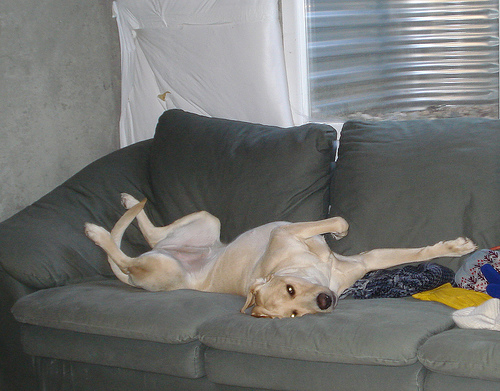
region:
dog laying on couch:
[83, 25, 482, 387]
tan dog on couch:
[3, 134, 335, 379]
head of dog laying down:
[226, 259, 355, 340]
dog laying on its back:
[8, 113, 424, 340]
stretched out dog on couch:
[46, 119, 421, 308]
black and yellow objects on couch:
[377, 270, 499, 321]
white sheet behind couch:
[61, 0, 355, 137]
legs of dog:
[317, 166, 437, 269]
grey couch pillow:
[145, 91, 342, 243]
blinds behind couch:
[273, 16, 477, 144]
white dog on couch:
[84, 191, 441, 327]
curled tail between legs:
[101, 190, 154, 277]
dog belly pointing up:
[196, 215, 296, 278]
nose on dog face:
[311, 279, 338, 318]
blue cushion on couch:
[145, 108, 342, 223]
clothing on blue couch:
[349, 242, 497, 315]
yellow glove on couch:
[408, 274, 495, 310]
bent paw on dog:
[293, 208, 360, 248]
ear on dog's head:
[236, 275, 268, 323]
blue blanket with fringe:
[348, 258, 456, 303]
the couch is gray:
[347, 317, 362, 349]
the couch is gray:
[319, 328, 332, 343]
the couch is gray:
[353, 363, 363, 373]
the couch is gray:
[367, 360, 375, 380]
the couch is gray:
[346, 337, 363, 377]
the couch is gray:
[338, 358, 354, 388]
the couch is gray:
[354, 339, 369, 371]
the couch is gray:
[355, 340, 375, 383]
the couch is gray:
[360, 325, 377, 368]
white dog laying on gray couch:
[58, 181, 488, 385]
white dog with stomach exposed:
[83, 166, 489, 324]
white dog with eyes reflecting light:
[241, 262, 343, 324]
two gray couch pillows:
[148, 106, 496, 213]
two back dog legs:
[81, 189, 222, 283]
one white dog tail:
[109, 195, 149, 283]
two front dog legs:
[270, 216, 475, 266]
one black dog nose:
[312, 288, 335, 312]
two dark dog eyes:
[281, 279, 306, 319]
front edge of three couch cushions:
[8, 323, 498, 385]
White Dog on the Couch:
[91, 178, 381, 320]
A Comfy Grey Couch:
[0, 111, 498, 386]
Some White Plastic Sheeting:
[113, 5, 308, 126]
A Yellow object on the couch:
[413, 280, 490, 318]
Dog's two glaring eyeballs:
[285, 283, 306, 320]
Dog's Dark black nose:
[308, 287, 347, 312]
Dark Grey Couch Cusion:
[143, 98, 335, 243]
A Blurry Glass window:
[308, 2, 498, 117]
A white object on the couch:
[451, 293, 499, 340]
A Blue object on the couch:
[480, 259, 499, 301]